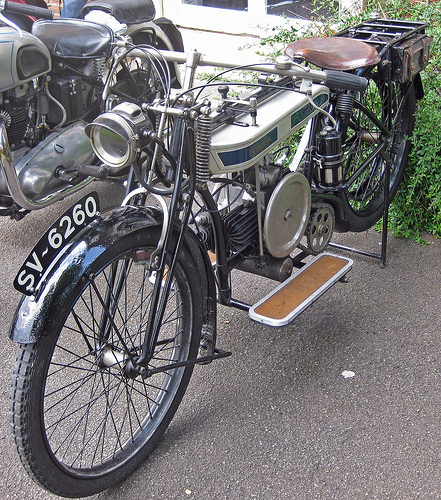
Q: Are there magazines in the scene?
A: No, there are no magazines.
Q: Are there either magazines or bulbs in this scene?
A: No, there are no magazines or bulbs.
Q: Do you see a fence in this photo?
A: No, there are no fences.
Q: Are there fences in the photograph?
A: No, there are no fences.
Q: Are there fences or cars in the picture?
A: No, there are no fences or cars.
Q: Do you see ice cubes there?
A: No, there are no ice cubes.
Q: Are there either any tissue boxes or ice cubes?
A: No, there are no ice cubes or tissue boxes.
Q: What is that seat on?
A: The seat is on the bike.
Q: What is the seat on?
A: The seat is on the bike.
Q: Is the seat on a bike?
A: Yes, the seat is on a bike.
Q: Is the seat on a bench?
A: No, the seat is on a bike.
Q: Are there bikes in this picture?
A: Yes, there is a bike.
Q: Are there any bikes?
A: Yes, there is a bike.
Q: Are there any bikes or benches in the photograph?
A: Yes, there is a bike.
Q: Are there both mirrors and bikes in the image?
A: No, there is a bike but no mirrors.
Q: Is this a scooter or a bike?
A: This is a bike.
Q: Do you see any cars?
A: No, there are no cars.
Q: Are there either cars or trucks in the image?
A: No, there are no cars or trucks.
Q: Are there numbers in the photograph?
A: Yes, there are numbers.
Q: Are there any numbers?
A: Yes, there are numbers.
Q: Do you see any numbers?
A: Yes, there are numbers.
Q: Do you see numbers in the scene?
A: Yes, there are numbers.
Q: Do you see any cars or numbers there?
A: Yes, there are numbers.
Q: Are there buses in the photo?
A: No, there are no buses.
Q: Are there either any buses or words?
A: No, there are no buses or words.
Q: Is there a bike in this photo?
A: Yes, there is a bike.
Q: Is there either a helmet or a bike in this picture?
A: Yes, there is a bike.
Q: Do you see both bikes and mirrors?
A: No, there is a bike but no mirrors.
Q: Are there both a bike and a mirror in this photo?
A: No, there is a bike but no mirrors.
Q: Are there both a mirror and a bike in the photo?
A: No, there is a bike but no mirrors.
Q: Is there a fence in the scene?
A: No, there are no fences.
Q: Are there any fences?
A: No, there are no fences.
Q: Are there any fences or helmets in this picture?
A: No, there are no fences or helmets.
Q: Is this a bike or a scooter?
A: This is a bike.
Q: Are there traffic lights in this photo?
A: No, there are no traffic lights.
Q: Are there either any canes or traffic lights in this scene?
A: No, there are no traffic lights or canes.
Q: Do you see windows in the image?
A: Yes, there is a window.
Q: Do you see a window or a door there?
A: Yes, there is a window.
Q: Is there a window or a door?
A: Yes, there is a window.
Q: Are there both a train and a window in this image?
A: No, there is a window but no trains.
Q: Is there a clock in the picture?
A: No, there are no clocks.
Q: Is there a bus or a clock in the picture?
A: No, there are no clocks or buses.